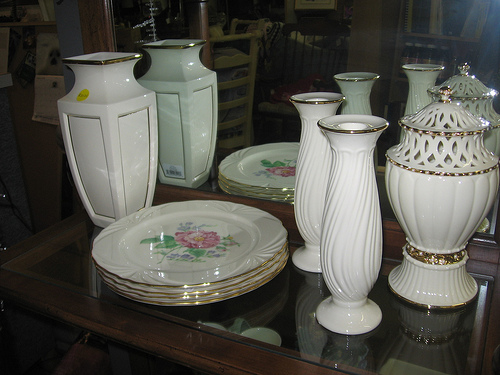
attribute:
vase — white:
[65, 55, 161, 221]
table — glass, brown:
[4, 191, 484, 375]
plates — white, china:
[92, 199, 291, 306]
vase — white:
[398, 90, 484, 309]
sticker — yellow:
[78, 87, 89, 101]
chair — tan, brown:
[270, 23, 333, 106]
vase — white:
[316, 120, 385, 327]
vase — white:
[287, 93, 334, 272]